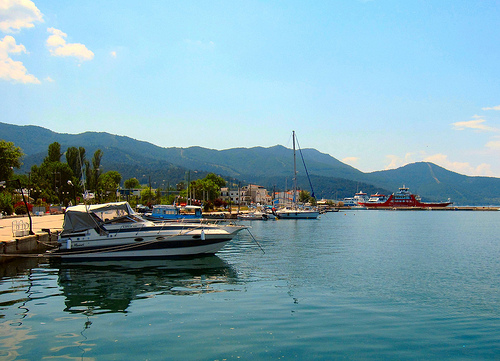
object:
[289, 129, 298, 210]
mast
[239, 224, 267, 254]
cable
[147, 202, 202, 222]
cabin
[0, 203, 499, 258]
harbor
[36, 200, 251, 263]
boat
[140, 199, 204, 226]
boat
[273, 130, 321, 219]
boat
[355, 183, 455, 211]
boat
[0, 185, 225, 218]
field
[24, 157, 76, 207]
tree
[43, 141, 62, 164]
tree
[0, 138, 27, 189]
tree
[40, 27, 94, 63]
cloud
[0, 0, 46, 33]
cloud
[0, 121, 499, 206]
mountains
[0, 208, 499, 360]
water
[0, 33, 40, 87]
clouds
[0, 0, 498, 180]
sky